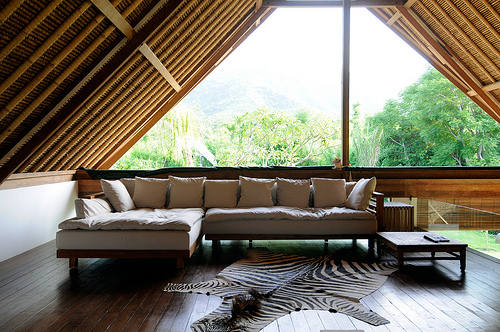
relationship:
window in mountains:
[108, 4, 498, 169] [146, 70, 356, 127]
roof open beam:
[12, 8, 159, 116] [341, 0, 350, 165]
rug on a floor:
[156, 242, 399, 329] [0, 238, 499, 329]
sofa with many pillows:
[41, 166, 383, 276] [94, 165, 369, 213]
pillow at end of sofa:
[346, 172, 380, 212] [52, 168, 384, 267]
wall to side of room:
[0, 177, 59, 239] [4, 4, 484, 329]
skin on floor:
[159, 231, 416, 329] [0, 204, 484, 315]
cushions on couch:
[100, 174, 377, 211] [57, 176, 384, 268]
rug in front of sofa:
[161, 251, 399, 332] [59, 157, 391, 270]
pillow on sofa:
[100, 179, 135, 210] [52, 168, 384, 267]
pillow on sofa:
[133, 176, 169, 206] [52, 168, 384, 267]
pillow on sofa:
[168, 174, 205, 208] [52, 168, 384, 267]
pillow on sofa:
[203, 178, 238, 208] [52, 168, 384, 267]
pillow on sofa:
[236, 175, 276, 207] [52, 168, 384, 267]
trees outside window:
[159, 69, 497, 158] [87, 6, 493, 176]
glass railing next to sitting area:
[428, 198, 499, 259] [20, 141, 479, 309]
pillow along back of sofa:
[131, 176, 169, 209] [41, 166, 383, 276]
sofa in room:
[55, 166, 384, 269] [4, 4, 484, 329]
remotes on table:
[421, 228, 444, 244] [377, 222, 485, 259]